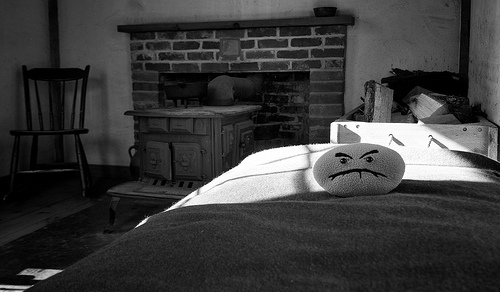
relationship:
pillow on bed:
[308, 141, 410, 195] [238, 137, 478, 289]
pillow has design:
[308, 141, 410, 195] [322, 147, 386, 183]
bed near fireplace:
[25, 142, 498, 289] [110, 10, 331, 170]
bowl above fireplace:
[313, 7, 338, 16] [116, 15, 354, 181]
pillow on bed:
[308, 141, 410, 195] [77, 125, 465, 288]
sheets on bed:
[22, 146, 497, 292] [25, 142, 498, 289]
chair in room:
[0, 66, 95, 197] [0, 1, 497, 290]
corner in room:
[2, 4, 121, 174] [0, 1, 497, 290]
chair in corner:
[0, 66, 95, 197] [2, 4, 121, 174]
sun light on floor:
[6, 253, 83, 281] [1, 173, 150, 290]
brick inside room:
[250, 30, 350, 49] [59, 9, 500, 281]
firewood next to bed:
[348, 67, 489, 151] [76, 147, 498, 284]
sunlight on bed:
[199, 142, 481, 212] [145, 135, 491, 289]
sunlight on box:
[329, 78, 496, 165] [330, 113, 495, 153]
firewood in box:
[333, 43, 488, 137] [330, 113, 495, 153]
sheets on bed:
[208, 124, 445, 290] [25, 142, 498, 289]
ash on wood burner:
[168, 104, 248, 114] [117, 100, 259, 190]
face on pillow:
[311, 138, 397, 187] [309, 142, 389, 204]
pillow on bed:
[275, 126, 417, 206] [79, 111, 490, 288]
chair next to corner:
[8, 66, 150, 178] [0, 2, 120, 203]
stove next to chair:
[97, 75, 273, 226] [18, 55, 116, 217]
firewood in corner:
[336, 60, 488, 123] [327, 2, 498, 149]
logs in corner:
[328, 67, 476, 145] [409, 44, 499, 148]